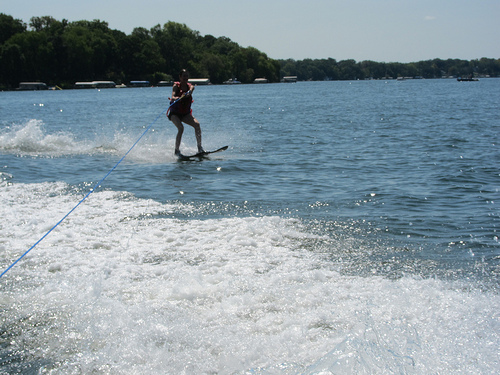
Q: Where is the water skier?
A: A lake.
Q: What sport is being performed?
A: Water skiing.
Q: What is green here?
A: The trees.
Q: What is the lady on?
A: A ski.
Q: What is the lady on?
A: Water.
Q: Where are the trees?
A: Behind the lake.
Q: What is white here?
A: The waves.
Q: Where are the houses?
A: Below the trees.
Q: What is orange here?
A: Jacket.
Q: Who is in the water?
A: A person.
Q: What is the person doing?
A: Skiing in water.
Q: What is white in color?
A: Some of the water.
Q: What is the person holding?
A: A rope.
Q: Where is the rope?
A: In front of person.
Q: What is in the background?
A: Many trees.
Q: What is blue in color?
A: Rope.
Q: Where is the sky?
A: Above the land.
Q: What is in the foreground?
A: White water.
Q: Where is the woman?
A: In the lake.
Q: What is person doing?
A: Water skiing.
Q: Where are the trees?
A: Beside ocean.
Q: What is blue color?
A: Water.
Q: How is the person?
A: Wet.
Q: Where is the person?
A: In water.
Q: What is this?
A: A water skier.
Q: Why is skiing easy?
A: Water is calm.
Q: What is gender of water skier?
A: Male.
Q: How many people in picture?
A: One.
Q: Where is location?
A: On a lake.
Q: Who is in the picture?
A: A water skier.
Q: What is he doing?
A: Skiing.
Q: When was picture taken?
A: During daylight.